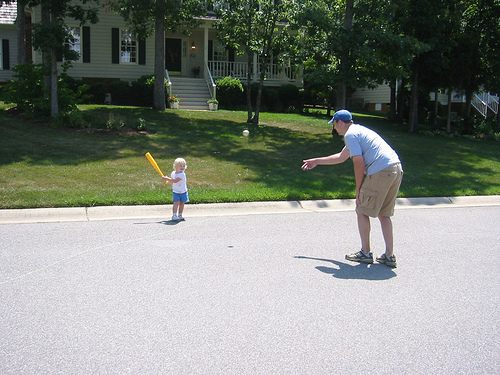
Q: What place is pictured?
A: It is a street.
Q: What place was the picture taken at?
A: It was taken at the street.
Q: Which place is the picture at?
A: It is at the street.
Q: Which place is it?
A: It is a street.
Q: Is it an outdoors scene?
A: Yes, it is outdoors.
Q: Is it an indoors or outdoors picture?
A: It is outdoors.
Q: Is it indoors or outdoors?
A: It is outdoors.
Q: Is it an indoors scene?
A: No, it is outdoors.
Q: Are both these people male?
A: No, they are both male and female.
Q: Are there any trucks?
A: No, there are no trucks.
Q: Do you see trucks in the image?
A: No, there are no trucks.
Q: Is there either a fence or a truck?
A: No, there are no trucks or fences.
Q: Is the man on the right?
A: Yes, the man is on the right of the image.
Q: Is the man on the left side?
A: No, the man is on the right of the image.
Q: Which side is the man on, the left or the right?
A: The man is on the right of the image.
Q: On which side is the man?
A: The man is on the right of the image.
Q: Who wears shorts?
A: The man wears shorts.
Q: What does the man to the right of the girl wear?
A: The man wears shorts.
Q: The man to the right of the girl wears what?
A: The man wears shorts.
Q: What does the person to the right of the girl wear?
A: The man wears shorts.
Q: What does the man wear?
A: The man wears shorts.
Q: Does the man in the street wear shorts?
A: Yes, the man wears shorts.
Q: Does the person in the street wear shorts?
A: Yes, the man wears shorts.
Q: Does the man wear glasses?
A: No, the man wears shorts.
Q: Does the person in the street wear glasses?
A: No, the man wears shorts.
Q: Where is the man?
A: The man is in the street.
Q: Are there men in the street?
A: Yes, there is a man in the street.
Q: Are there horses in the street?
A: No, there is a man in the street.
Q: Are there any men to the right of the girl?
A: Yes, there is a man to the right of the girl.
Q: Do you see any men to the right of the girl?
A: Yes, there is a man to the right of the girl.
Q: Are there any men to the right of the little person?
A: Yes, there is a man to the right of the girl.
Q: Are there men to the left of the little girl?
A: No, the man is to the right of the girl.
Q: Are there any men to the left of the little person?
A: No, the man is to the right of the girl.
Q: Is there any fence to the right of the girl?
A: No, there is a man to the right of the girl.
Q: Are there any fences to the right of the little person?
A: No, there is a man to the right of the girl.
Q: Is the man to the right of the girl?
A: Yes, the man is to the right of the girl.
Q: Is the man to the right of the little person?
A: Yes, the man is to the right of the girl.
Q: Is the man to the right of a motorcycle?
A: No, the man is to the right of the girl.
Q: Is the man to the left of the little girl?
A: No, the man is to the right of the girl.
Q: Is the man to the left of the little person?
A: No, the man is to the right of the girl.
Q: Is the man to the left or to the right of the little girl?
A: The man is to the right of the girl.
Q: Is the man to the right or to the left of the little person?
A: The man is to the right of the girl.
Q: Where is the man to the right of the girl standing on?
A: The man is standing on the street.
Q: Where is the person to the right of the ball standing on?
A: The man is standing on the street.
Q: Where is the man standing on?
A: The man is standing on the street.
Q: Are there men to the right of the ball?
A: Yes, there is a man to the right of the ball.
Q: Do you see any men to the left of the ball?
A: No, the man is to the right of the ball.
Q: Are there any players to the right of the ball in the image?
A: No, there is a man to the right of the ball.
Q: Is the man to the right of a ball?
A: Yes, the man is to the right of a ball.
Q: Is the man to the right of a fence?
A: No, the man is to the right of a ball.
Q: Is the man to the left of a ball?
A: No, the man is to the right of a ball.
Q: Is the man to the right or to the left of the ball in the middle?
A: The man is to the right of the ball.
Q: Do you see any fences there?
A: No, there are no fences.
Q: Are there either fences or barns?
A: No, there are no fences or barns.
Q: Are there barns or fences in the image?
A: No, there are no fences or barns.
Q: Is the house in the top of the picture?
A: Yes, the house is in the top of the image.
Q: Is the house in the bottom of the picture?
A: No, the house is in the top of the image.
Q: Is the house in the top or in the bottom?
A: The house is in the top of the image.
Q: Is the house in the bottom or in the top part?
A: The house is in the top of the image.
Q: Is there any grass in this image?
A: Yes, there is grass.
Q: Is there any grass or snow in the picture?
A: Yes, there is grass.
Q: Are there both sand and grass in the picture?
A: No, there is grass but no sand.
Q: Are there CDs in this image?
A: No, there are no cds.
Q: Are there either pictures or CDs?
A: No, there are no CDs or pictures.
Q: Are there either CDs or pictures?
A: No, there are no CDs or pictures.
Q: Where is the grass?
A: The grass is on the ground.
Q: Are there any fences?
A: No, there are no fences.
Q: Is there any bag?
A: No, there are no bags.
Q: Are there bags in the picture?
A: No, there are no bags.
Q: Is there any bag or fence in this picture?
A: No, there are no bags or fences.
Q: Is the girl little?
A: Yes, the girl is little.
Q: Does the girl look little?
A: Yes, the girl is little.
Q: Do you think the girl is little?
A: Yes, the girl is little.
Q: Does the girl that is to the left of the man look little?
A: Yes, the girl is little.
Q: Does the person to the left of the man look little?
A: Yes, the girl is little.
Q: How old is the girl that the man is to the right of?
A: The girl is little.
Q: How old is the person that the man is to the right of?
A: The girl is little.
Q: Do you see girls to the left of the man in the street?
A: Yes, there is a girl to the left of the man.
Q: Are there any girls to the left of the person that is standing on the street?
A: Yes, there is a girl to the left of the man.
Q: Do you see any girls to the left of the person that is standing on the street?
A: Yes, there is a girl to the left of the man.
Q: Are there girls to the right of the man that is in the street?
A: No, the girl is to the left of the man.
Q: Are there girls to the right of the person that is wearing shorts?
A: No, the girl is to the left of the man.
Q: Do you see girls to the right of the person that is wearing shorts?
A: No, the girl is to the left of the man.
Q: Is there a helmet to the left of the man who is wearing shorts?
A: No, there is a girl to the left of the man.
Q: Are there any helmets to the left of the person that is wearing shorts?
A: No, there is a girl to the left of the man.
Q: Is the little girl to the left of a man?
A: Yes, the girl is to the left of a man.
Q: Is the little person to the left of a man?
A: Yes, the girl is to the left of a man.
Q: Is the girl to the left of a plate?
A: No, the girl is to the left of a man.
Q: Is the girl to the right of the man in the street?
A: No, the girl is to the left of the man.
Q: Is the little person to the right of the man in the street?
A: No, the girl is to the left of the man.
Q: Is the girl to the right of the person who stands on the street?
A: No, the girl is to the left of the man.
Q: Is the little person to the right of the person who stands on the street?
A: No, the girl is to the left of the man.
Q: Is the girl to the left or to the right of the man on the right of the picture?
A: The girl is to the left of the man.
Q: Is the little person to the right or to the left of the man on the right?
A: The girl is to the left of the man.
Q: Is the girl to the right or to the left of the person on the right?
A: The girl is to the left of the man.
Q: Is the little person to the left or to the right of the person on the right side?
A: The girl is to the left of the man.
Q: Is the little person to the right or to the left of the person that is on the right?
A: The girl is to the left of the man.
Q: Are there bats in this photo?
A: Yes, there is a bat.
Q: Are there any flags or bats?
A: Yes, there is a bat.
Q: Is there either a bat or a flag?
A: Yes, there is a bat.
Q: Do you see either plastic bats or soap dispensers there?
A: Yes, there is a plastic bat.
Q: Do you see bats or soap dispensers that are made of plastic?
A: Yes, the bat is made of plastic.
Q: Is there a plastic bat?
A: Yes, there is a bat that is made of plastic.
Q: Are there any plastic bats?
A: Yes, there is a bat that is made of plastic.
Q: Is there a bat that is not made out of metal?
A: Yes, there is a bat that is made of plastic.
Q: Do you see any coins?
A: No, there are no coins.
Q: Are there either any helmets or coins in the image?
A: No, there are no coins or helmets.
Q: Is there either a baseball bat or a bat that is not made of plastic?
A: No, there is a bat but it is made of plastic.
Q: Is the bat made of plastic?
A: Yes, the bat is made of plastic.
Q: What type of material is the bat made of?
A: The bat is made of plastic.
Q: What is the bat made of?
A: The bat is made of plastic.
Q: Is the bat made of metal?
A: No, the bat is made of plastic.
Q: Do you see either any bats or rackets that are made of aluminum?
A: No, there is a bat but it is made of plastic.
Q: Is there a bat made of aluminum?
A: No, there is a bat but it is made of plastic.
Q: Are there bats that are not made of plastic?
A: No, there is a bat but it is made of plastic.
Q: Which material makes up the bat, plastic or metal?
A: The bat is made of plastic.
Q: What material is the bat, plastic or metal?
A: The bat is made of plastic.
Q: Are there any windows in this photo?
A: Yes, there is a window.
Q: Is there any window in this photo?
A: Yes, there is a window.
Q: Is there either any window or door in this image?
A: Yes, there is a window.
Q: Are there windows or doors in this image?
A: Yes, there is a window.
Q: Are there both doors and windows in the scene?
A: Yes, there are both a window and a door.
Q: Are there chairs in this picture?
A: No, there are no chairs.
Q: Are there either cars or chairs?
A: No, there are no chairs or cars.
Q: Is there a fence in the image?
A: No, there are no fences.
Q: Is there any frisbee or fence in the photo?
A: No, there are no fences or frisbees.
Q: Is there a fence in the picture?
A: No, there are no fences.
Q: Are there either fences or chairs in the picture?
A: No, there are no fences or chairs.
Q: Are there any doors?
A: Yes, there is a door.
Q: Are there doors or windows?
A: Yes, there is a door.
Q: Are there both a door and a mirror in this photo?
A: No, there is a door but no mirrors.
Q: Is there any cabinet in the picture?
A: No, there are no cabinets.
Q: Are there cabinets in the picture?
A: No, there are no cabinets.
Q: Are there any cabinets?
A: No, there are no cabinets.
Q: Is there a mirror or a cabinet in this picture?
A: No, there are no cabinets or mirrors.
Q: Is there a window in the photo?
A: Yes, there is a window.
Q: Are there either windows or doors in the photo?
A: Yes, there is a window.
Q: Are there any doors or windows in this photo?
A: Yes, there is a window.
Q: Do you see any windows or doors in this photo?
A: Yes, there is a window.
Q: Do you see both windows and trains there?
A: No, there is a window but no trains.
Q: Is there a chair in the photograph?
A: No, there are no chairs.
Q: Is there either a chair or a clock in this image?
A: No, there are no chairs or clocks.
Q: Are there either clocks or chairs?
A: No, there are no chairs or clocks.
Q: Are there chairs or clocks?
A: No, there are no chairs or clocks.